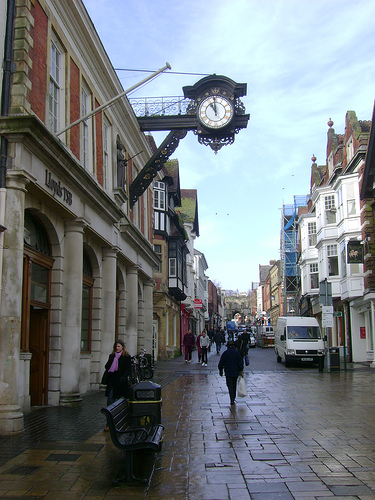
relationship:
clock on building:
[182, 73, 252, 153] [3, 4, 155, 437]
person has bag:
[216, 337, 251, 407] [237, 376, 251, 397]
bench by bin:
[104, 395, 164, 487] [126, 380, 165, 425]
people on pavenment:
[180, 319, 263, 407] [2, 331, 374, 493]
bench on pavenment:
[104, 395, 164, 487] [2, 331, 374, 493]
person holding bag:
[216, 337, 251, 407] [237, 376, 251, 397]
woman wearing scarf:
[100, 336, 130, 402] [104, 349, 126, 372]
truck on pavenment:
[274, 315, 328, 371] [2, 331, 374, 493]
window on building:
[112, 153, 131, 194] [3, 4, 155, 437]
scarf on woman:
[104, 349, 126, 372] [100, 336, 130, 402]